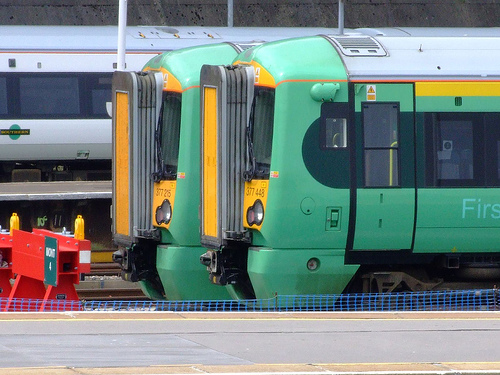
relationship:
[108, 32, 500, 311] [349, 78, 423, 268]
train has door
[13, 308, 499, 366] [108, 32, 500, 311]
road by train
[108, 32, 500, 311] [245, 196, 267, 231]
train has headlight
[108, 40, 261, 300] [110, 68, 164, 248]
train has doorway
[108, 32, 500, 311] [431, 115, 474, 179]
train has window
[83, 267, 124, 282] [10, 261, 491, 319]
gravel along tracks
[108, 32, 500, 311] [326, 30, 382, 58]
train has vent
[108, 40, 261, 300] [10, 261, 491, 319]
train on tracks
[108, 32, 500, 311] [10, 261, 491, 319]
train on tracks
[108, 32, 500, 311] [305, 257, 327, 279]
train has light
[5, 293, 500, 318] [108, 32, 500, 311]
netting side of train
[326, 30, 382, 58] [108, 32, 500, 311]
vent on top of train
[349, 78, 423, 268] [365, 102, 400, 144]
door has window